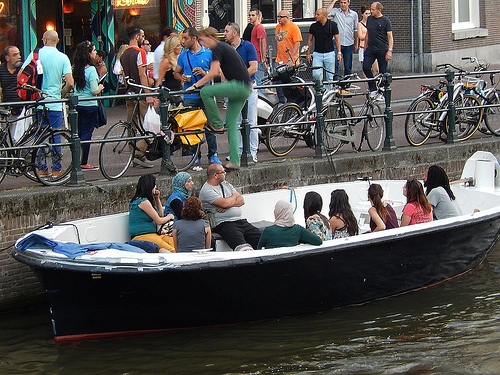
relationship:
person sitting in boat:
[129, 175, 176, 253] [10, 151, 499, 340]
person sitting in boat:
[174, 199, 213, 256] [10, 151, 499, 340]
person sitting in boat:
[329, 190, 358, 240] [10, 151, 499, 340]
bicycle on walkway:
[0, 84, 73, 185] [0, 63, 499, 191]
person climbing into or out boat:
[187, 28, 251, 172] [10, 151, 499, 340]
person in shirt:
[15, 29, 74, 178] [23, 46, 73, 113]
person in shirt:
[73, 40, 107, 171] [74, 65, 101, 106]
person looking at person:
[174, 199, 213, 256] [187, 28, 251, 172]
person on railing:
[187, 28, 251, 172] [0, 68, 499, 189]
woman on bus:
[255, 201, 323, 250] [10, 151, 499, 340]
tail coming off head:
[369, 192, 388, 220] [368, 183, 384, 203]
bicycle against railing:
[0, 84, 73, 185] [0, 68, 499, 189]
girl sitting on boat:
[329, 190, 358, 240] [10, 151, 499, 340]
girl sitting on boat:
[306, 192, 333, 243] [10, 151, 499, 340]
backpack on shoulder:
[16, 50, 43, 108] [25, 47, 50, 67]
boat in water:
[10, 151, 499, 340] [2, 238, 498, 374]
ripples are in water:
[255, 289, 499, 372] [2, 238, 498, 374]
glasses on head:
[278, 15, 290, 20] [278, 8, 290, 25]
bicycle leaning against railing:
[0, 84, 73, 185] [0, 68, 499, 189]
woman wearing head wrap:
[255, 201, 323, 250] [273, 201, 295, 227]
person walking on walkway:
[73, 40, 107, 171] [0, 63, 499, 191]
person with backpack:
[15, 29, 74, 178] [16, 50, 43, 108]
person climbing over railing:
[187, 28, 251, 172] [0, 68, 499, 189]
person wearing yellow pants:
[129, 175, 176, 253] [133, 233, 176, 251]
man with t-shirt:
[275, 9, 302, 105] [275, 22, 302, 65]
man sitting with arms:
[198, 163, 260, 250] [199, 186, 245, 209]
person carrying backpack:
[15, 29, 74, 178] [16, 50, 43, 108]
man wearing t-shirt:
[275, 9, 302, 105] [275, 22, 302, 65]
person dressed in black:
[362, 4, 395, 93] [363, 16, 394, 107]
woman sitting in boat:
[255, 201, 323, 250] [10, 151, 499, 340]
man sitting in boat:
[198, 163, 260, 250] [10, 151, 499, 340]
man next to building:
[275, 9, 302, 105] [174, 0, 334, 70]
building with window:
[350, 1, 498, 73] [451, 0, 480, 34]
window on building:
[451, 0, 480, 34] [350, 1, 498, 73]